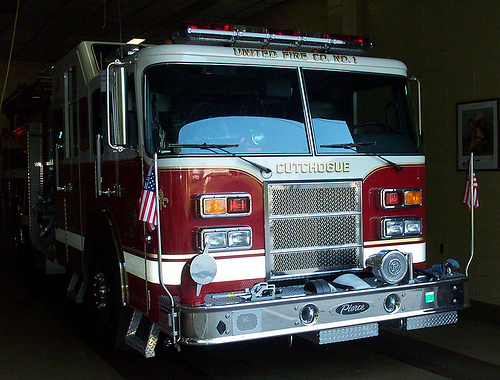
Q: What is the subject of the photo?
A: Truck.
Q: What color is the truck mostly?
A: Red.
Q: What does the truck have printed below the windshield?
A: Cutchogue.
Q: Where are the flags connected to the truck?
A: Bumper.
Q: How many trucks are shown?
A: One.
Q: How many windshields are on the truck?
A: Two.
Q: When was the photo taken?
A: Daytime.